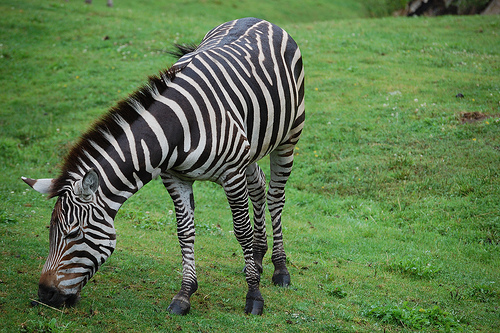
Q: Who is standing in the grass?
A: A zebra.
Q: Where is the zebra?
A: Standing in the grass/.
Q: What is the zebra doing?
A: Putting his nose to the ground.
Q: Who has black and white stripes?
A: Zebra.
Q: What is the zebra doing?
A: Grazing.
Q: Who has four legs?
A: A zebra.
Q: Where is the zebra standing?
A: On grass.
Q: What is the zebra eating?
A: Grass.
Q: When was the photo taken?
A: During the daytime.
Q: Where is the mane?
A: On zebra's neck.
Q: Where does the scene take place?
A: On grass field.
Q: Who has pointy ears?
A: The zebra.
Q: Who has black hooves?
A: Zebra.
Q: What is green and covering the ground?
A: Grass.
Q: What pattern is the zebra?
A: Striped.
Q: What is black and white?
A: A zebra.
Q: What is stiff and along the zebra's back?
A: A mane.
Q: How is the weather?
A: Clear.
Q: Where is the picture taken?
A: Field.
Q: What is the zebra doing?
A: Grazing.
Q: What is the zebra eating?
A: Grass.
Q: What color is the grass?
A: Green.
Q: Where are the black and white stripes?
A: On the zebra.